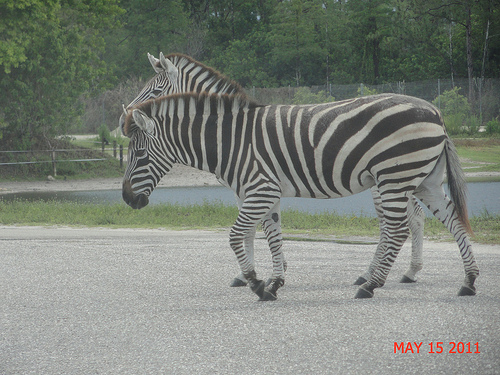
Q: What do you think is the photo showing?
A: It is showing a pavement.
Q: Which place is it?
A: It is a pavement.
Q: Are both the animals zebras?
A: Yes, all the animals are zebras.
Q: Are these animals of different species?
A: No, all the animals are zebras.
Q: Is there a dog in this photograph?
A: No, there are no dogs.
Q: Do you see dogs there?
A: No, there are no dogs.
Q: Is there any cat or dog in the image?
A: No, there are no dogs or cats.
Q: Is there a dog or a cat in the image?
A: No, there are no dogs or cats.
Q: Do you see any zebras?
A: Yes, there is a zebra.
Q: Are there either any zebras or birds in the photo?
A: Yes, there is a zebra.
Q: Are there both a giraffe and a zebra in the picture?
A: No, there is a zebra but no giraffes.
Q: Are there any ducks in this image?
A: No, there are no ducks.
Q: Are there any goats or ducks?
A: No, there are no ducks or goats.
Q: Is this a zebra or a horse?
A: This is a zebra.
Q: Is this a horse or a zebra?
A: This is a zebra.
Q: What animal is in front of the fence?
A: The zebra is in front of the fence.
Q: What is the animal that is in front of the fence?
A: The animal is a zebra.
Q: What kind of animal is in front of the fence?
A: The animal is a zebra.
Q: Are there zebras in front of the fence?
A: Yes, there is a zebra in front of the fence.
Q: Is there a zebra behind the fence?
A: No, the zebra is in front of the fence.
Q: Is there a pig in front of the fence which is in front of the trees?
A: No, there is a zebra in front of the fence.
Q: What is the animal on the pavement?
A: The animal is a zebra.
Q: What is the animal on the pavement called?
A: The animal is a zebra.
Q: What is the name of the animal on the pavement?
A: The animal is a zebra.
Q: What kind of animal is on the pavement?
A: The animal is a zebra.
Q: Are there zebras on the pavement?
A: Yes, there is a zebra on the pavement.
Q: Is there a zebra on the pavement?
A: Yes, there is a zebra on the pavement.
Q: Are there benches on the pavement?
A: No, there is a zebra on the pavement.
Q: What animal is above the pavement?
A: The animal is a zebra.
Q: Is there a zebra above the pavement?
A: Yes, there is a zebra above the pavement.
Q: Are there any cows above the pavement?
A: No, there is a zebra above the pavement.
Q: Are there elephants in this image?
A: No, there are no elephants.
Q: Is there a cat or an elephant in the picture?
A: No, there are no elephants or cats.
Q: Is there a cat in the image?
A: No, there are no cats.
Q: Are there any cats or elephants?
A: No, there are no cats or elephants.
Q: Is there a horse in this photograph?
A: No, there are no horses.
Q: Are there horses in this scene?
A: No, there are no horses.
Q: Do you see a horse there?
A: No, there are no horses.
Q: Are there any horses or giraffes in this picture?
A: No, there are no horses or giraffes.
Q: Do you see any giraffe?
A: No, there are no giraffes.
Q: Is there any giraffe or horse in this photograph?
A: No, there are no giraffes or horses.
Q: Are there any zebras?
A: Yes, there is a zebra.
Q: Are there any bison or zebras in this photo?
A: Yes, there is a zebra.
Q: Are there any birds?
A: No, there are no birds.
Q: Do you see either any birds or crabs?
A: No, there are no birds or crabs.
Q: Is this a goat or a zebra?
A: This is a zebra.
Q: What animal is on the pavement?
A: The zebra is on the pavement.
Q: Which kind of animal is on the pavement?
A: The animal is a zebra.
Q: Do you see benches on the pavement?
A: No, there is a zebra on the pavement.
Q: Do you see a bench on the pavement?
A: No, there is a zebra on the pavement.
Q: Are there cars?
A: No, there are no cars.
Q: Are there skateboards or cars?
A: No, there are no cars or skateboards.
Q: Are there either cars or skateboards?
A: No, there are no cars or skateboards.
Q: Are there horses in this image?
A: No, there are no horses.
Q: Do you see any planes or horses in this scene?
A: No, there are no horses or planes.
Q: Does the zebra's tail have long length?
A: Yes, the tail is long.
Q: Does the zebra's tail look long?
A: Yes, the tail is long.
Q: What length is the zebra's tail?
A: The tail is long.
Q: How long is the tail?
A: The tail is long.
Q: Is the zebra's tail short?
A: No, the tail is long.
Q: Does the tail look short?
A: No, the tail is long.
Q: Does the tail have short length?
A: No, the tail is long.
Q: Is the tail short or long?
A: The tail is long.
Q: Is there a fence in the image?
A: Yes, there is a fence.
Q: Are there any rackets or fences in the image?
A: Yes, there is a fence.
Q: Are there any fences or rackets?
A: Yes, there is a fence.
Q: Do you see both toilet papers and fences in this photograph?
A: No, there is a fence but no toilet papers.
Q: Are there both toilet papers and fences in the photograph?
A: No, there is a fence but no toilet papers.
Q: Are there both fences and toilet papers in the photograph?
A: No, there is a fence but no toilet papers.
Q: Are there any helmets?
A: No, there are no helmets.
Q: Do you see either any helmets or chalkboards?
A: No, there are no helmets or chalkboards.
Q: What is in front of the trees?
A: The fence is in front of the trees.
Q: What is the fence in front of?
A: The fence is in front of the trees.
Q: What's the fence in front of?
A: The fence is in front of the trees.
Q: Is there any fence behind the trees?
A: No, the fence is in front of the trees.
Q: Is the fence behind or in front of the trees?
A: The fence is in front of the trees.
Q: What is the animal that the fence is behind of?
A: The animal is a zebra.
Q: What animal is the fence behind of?
A: The fence is behind the zebra.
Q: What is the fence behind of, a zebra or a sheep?
A: The fence is behind a zebra.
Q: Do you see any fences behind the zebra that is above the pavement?
A: Yes, there is a fence behind the zebra.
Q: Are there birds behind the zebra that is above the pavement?
A: No, there is a fence behind the zebra.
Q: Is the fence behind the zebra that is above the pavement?
A: Yes, the fence is behind the zebra.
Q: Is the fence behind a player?
A: No, the fence is behind the zebra.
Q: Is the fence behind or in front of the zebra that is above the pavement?
A: The fence is behind the zebra.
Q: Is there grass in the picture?
A: Yes, there is grass.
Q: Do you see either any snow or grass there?
A: Yes, there is grass.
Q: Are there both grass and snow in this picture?
A: No, there is grass but no snow.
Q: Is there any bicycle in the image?
A: No, there are no bicycles.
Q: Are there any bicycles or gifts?
A: No, there are no bicycles or gifts.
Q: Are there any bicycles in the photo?
A: No, there are no bicycles.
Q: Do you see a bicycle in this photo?
A: No, there are no bicycles.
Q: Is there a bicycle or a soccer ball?
A: No, there are no bicycles or soccer balls.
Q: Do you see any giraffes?
A: No, there are no giraffes.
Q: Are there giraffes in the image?
A: No, there are no giraffes.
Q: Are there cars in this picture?
A: No, there are no cars.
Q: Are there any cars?
A: No, there are no cars.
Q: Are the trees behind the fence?
A: Yes, the trees are behind the fence.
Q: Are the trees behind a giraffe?
A: No, the trees are behind the fence.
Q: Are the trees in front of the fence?
A: No, the trees are behind the fence.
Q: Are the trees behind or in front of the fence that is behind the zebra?
A: The trees are behind the fence.